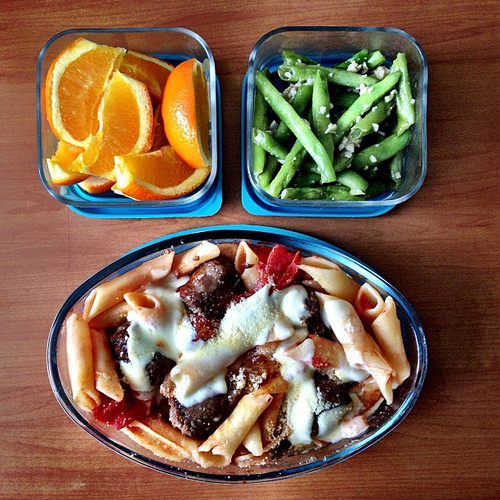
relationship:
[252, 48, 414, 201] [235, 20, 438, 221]
beans in a container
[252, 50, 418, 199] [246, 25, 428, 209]
beans in a bowl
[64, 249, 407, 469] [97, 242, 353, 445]
pasta with sauce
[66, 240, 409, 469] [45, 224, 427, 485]
pasta in a bowl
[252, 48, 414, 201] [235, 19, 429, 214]
beans in bowl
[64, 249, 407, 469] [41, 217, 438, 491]
pasta in bowl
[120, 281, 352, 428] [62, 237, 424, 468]
white sauce on pasta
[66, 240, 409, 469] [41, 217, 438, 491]
pasta on bowl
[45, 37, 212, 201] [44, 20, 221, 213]
orange in container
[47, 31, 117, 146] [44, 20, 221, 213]
orange in container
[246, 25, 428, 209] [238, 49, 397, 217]
bowl sitting on lid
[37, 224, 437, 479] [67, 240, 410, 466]
main dish has main dish